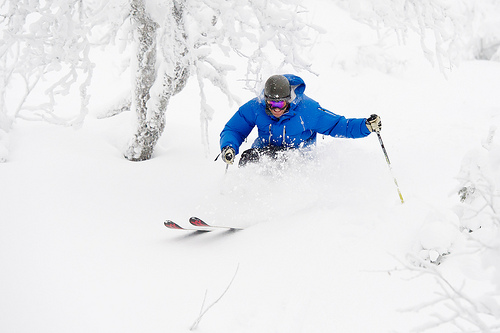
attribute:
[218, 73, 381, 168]
man — skiing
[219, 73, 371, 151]
coat — blue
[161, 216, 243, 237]
skis — red, black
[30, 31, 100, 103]
tree branches — snow-drenched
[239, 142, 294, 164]
pants — black, partially-visible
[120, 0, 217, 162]
tree trunk — snow covered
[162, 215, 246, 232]
skis — red, black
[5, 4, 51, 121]
tree — snow-covered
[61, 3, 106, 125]
tree — snow-covered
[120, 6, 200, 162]
tree — snow-covered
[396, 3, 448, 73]
tree — snow-covered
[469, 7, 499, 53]
tree — snow-covered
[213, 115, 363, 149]
jacket — blue, snow jacket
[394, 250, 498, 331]
branches — snow covered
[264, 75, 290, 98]
helmet — black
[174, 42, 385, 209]
jacket. — blue, puffy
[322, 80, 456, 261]
pole — ski, black, yellow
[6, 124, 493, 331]
snow — cloud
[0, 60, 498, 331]
snow — white